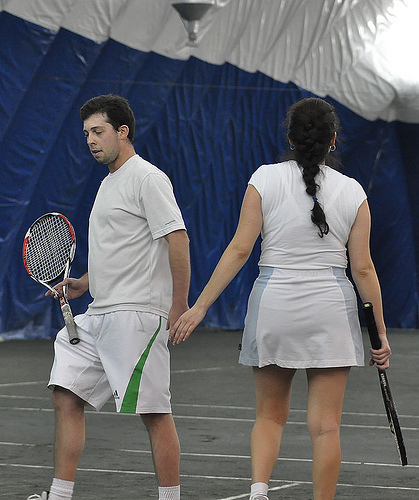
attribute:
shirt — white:
[83, 153, 188, 320]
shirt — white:
[247, 158, 367, 269]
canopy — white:
[242, 3, 417, 104]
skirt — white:
[236, 267, 365, 368]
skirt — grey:
[236, 263, 378, 346]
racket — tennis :
[4, 193, 91, 340]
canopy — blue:
[2, 3, 417, 325]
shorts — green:
[27, 294, 180, 439]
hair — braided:
[302, 113, 331, 237]